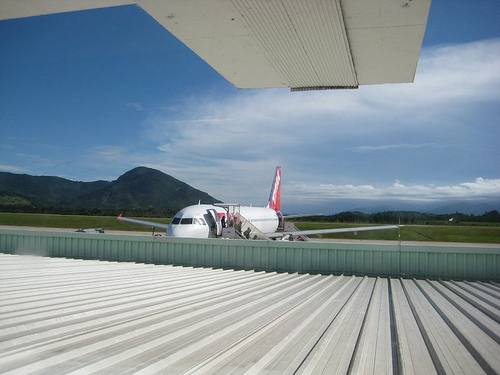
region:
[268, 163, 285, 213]
Red tail fin of a plane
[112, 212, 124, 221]
Red wing tip of a plane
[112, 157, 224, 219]
Mountain behind a plane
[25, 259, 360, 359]
White corrugated surface in front of a plane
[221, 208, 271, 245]
Passengers leaving a plane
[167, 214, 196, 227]
Windshield of a plane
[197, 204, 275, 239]
White body of a plane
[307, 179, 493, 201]
White clouds in a blue sky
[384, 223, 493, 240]
Green grass in an airport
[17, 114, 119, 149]
Blue sky above an airport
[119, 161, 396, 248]
airplane parked at airport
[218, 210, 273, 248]
stairs for passengers to exit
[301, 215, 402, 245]
wing on side of plane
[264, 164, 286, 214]
red tail with white lettering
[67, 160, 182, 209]
mountain with trees on horizon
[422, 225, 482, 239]
cut grass at airport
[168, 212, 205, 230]
windows on plane cockpit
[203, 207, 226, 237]
open door on side of plane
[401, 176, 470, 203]
white clouds low in sky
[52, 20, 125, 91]
deep blue daytime sky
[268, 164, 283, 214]
The red tail of the plane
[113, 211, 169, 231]
The left wing of the plane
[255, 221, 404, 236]
The right wing of the plane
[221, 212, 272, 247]
The people getting out of the front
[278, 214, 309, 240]
The staircase at the back of the plane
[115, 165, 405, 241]
The plane on the tarmac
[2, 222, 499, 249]
The tarmac the plane is on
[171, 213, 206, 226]
The windshields on the plane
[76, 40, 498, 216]
The clouds in the sky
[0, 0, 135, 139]
The open patch of blue sky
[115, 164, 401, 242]
a large white airplane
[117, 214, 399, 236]
the airplane's wing span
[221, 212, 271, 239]
people walking down the stairs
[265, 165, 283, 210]
the airplane has a red tail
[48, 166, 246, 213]
a mountain in the background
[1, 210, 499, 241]
the grass is green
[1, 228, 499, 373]
a white rooftop in the foreground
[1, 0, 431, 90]
a white canopy overhead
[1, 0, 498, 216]
the sky is blue and cloudy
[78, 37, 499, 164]
a cloud in the sky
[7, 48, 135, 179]
Blue sky above a mountain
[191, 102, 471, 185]
Clouds in a sky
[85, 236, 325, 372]
Roof on a building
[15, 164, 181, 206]
Brown mountain by an airport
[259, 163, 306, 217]
Red tail on a plane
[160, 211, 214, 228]
Windows on a plane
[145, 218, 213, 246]
Nose on a plane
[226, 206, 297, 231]
Windows on the side of a plane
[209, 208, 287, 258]
Stairs to a plane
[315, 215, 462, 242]
Grass by an airport